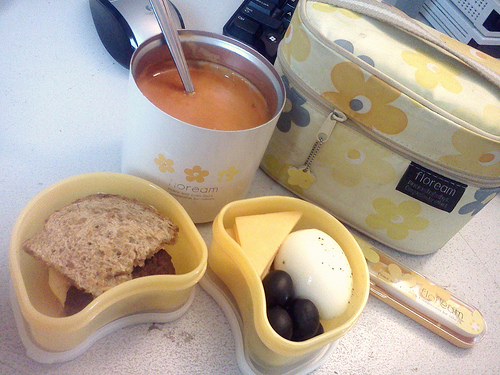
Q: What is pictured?
A: A lunch.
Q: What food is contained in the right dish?
A: Hard boiled egg, grapes and cheese.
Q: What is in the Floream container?
A: A soup.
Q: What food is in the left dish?
A: A sandwich.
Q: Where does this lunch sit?
A: On someone's desk.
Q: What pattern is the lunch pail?
A: Yellow floral.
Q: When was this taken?
A: During lunch break.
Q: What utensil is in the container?
A: A spoon.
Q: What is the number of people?
A: Zero.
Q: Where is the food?
A: On a desk.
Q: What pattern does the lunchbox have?
A: Flowers.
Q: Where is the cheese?
A: In a container.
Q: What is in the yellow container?
A: Partial sandwich with meat and egg.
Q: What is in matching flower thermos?
A: Tomato soup with spoon.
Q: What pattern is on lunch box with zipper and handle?
A: Flowered.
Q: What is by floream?
A: Flowered plastic utensils.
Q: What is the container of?
A: Tomato soup.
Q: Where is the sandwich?
A: In plastic container.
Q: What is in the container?
A: Cheese.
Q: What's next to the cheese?
A: Eggs.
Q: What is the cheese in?
A: A container.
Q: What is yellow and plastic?
A: A container.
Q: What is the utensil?
A: The spoon.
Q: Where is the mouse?
A: At the top.